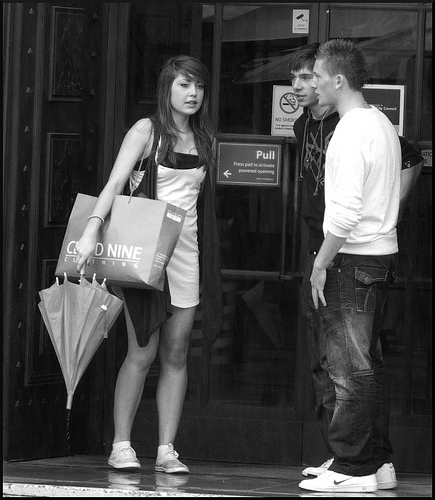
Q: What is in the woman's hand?
A: Umbrella.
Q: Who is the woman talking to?
A: Two men.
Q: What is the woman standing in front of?
A: Building.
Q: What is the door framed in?
A: Metal.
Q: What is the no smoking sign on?
A: Door.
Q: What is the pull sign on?
A: Door.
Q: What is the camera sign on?
A: Door.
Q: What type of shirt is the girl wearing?
A: Tank top.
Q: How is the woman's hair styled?
A: Straight.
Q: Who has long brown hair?
A: The girl.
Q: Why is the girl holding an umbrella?
A: It is raining.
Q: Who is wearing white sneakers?
A: The two guys.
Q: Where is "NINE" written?
A: On a bag.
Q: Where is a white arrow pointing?
A: To the left.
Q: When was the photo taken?
A: During the daytime.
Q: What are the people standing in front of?
A: Glass doors.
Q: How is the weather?
A: Raining.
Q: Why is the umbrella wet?
A: Rain.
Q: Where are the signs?
A: On the door.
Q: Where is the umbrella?
A: In the girl's hand.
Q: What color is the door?
A: Black.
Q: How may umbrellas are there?
A: One.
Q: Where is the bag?
A: On the girl's shoulder.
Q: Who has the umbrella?
A: The girl.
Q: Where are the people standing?
A: By the door.